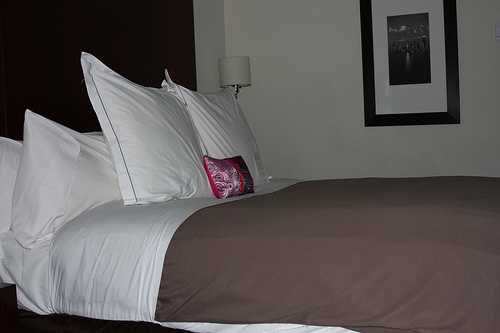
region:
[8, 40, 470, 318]
a bed with white pillows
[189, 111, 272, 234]
a small pink pillow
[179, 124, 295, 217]
a small decorative pillow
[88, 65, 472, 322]
a brown blanet on a bed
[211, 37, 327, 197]
a lamp next to a bed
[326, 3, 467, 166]
a picture on a while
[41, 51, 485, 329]
this is a bed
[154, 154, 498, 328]
taupe comforter on bed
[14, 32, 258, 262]
multiple pillows on bed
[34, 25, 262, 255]
the pillows are white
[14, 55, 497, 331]
the bed is made up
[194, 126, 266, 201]
pink pillow on bed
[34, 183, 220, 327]
white sheet on bed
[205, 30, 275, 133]
lamp next to bed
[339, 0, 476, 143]
picture on the wall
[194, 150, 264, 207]
Small pillow on the bed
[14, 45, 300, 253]
Main white pillows on the bed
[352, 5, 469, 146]
Picture on the wall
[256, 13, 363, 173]
Wall painted pure white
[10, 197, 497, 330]
Blankets tucked under the bed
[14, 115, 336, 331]
Sheet is turned down over blanket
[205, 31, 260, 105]
Lamp in corner is not on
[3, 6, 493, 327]
Simple yet comfortable room with bed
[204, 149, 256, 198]
small pink decorative pillow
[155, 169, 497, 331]
brown blanket covering the bed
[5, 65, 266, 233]
white pillows at the head of the bed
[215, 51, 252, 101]
a lamp next to the bed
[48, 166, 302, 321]
white sheet folded over the brown blanket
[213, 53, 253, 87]
white lampshade of a lamp near the bed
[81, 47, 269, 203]
two large white pillows on the bed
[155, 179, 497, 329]
brown blanket tucked in on the sides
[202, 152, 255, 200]
the small pink pillow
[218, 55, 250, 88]
the white lamp shade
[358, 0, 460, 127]
the picture is hanging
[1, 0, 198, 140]
the dark head board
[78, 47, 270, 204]
the two pillows behind the pink pillow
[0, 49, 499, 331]
the made up bed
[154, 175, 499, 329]
the brown colored blanket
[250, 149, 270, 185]
the small white piece of paper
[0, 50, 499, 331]
the pillows on the bed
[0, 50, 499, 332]
the made up beds with a lot of pillows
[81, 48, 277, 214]
two fluffy white bed pillows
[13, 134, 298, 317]
white cotton sheets on bed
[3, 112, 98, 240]
two extra bed pillows on bed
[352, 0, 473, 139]
a framed black and white picture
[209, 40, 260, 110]
a small lamp with a white lampshade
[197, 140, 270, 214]
a shiny colorful pillow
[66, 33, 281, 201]
two large white pillows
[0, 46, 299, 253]
a stack of pillows on a bed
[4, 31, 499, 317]
a bed with several pillows and sheets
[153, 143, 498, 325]
a brown comforter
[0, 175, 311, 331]
a white folded sheet on a bed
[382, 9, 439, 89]
a small black and white picture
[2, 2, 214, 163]
a dark colored headboard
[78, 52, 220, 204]
white pillow on bed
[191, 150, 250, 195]
pink colored pillow on the bed